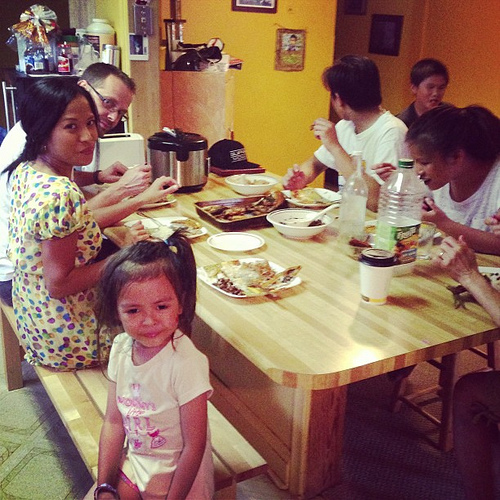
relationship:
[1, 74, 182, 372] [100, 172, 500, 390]
lady sitting at table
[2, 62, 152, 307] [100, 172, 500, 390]
man sitting at table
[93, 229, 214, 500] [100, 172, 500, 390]
girl sitting at table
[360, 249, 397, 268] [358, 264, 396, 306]
lid on top of cup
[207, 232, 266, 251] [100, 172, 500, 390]
plate on top of table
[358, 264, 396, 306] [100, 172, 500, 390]
cup on top of table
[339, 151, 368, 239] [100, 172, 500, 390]
bottle on top of table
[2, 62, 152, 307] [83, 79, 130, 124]
man wearing eyeglass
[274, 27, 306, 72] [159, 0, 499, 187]
picture hanging on wall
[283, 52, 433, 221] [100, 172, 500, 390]
guy sitting at table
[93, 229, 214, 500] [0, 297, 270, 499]
girl sitting on bench